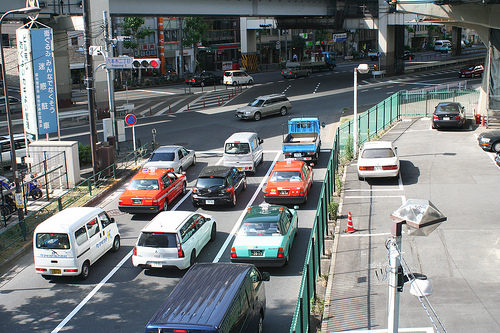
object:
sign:
[16, 28, 56, 135]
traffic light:
[133, 59, 159, 69]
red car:
[262, 159, 315, 205]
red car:
[118, 168, 189, 214]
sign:
[125, 115, 136, 126]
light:
[150, 60, 158, 67]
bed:
[290, 137, 317, 143]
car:
[432, 102, 466, 129]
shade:
[0, 278, 180, 330]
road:
[0, 59, 341, 331]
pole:
[1, 7, 24, 231]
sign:
[13, 192, 26, 210]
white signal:
[107, 58, 160, 69]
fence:
[283, 86, 476, 328]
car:
[32, 206, 121, 279]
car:
[225, 131, 263, 169]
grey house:
[146, 261, 271, 331]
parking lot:
[337, 196, 407, 235]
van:
[34, 206, 123, 280]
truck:
[283, 116, 326, 163]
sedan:
[191, 165, 248, 208]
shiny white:
[363, 158, 394, 165]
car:
[357, 141, 399, 178]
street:
[313, 115, 498, 330]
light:
[349, 63, 370, 155]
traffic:
[119, 117, 322, 333]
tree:
[21, 272, 151, 333]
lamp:
[0, 2, 62, 234]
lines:
[340, 229, 394, 239]